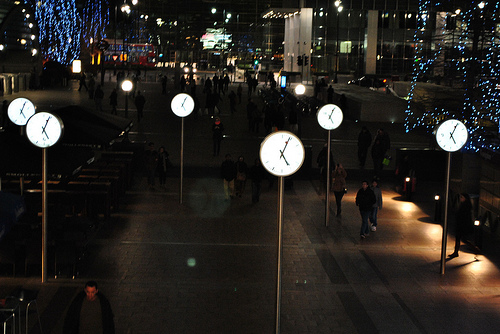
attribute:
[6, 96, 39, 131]
clocks — white, black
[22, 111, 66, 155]
clocks — white, black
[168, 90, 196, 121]
clocks — white, black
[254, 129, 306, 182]
clocks — white, black, tall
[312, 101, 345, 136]
clocks — white, black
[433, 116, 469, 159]
clocks — white, black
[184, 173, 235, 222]
reflection — light, clock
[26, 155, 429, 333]
pathway — large, brick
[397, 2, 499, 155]
lights — blue, on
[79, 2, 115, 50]
lights — blue, on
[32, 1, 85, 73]
lights — blue, on, small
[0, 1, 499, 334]
picture — night time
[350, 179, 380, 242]
people — walking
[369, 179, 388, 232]
people — walking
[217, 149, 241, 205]
people — walking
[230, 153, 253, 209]
people — walking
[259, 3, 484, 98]
buildings — decorated, lit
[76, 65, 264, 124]
crowd — distance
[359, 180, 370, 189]
hair — black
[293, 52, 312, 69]
lights — traffic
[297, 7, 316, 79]
columns — white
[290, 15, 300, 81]
columns — white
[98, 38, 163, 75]
bus — double-decker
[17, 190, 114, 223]
table — black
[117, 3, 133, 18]
lights — tall